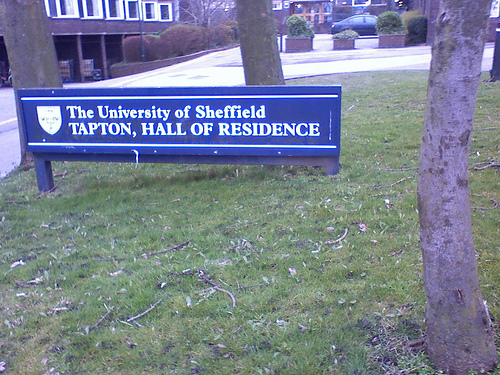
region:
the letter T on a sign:
[61, 100, 78, 121]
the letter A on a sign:
[76, 123, 88, 138]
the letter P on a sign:
[86, 120, 98, 135]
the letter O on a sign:
[107, 120, 119, 136]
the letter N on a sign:
[118, 120, 130, 134]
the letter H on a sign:
[140, 120, 154, 138]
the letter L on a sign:
[162, 120, 176, 135]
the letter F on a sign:
[201, 119, 214, 136]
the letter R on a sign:
[218, 121, 230, 138]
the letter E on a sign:
[229, 120, 241, 137]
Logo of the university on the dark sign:
[33, 102, 63, 137]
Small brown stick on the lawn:
[192, 265, 247, 310]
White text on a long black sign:
[57, 100, 322, 142]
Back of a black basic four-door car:
[327, 13, 383, 36]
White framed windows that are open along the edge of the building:
[45, 0, 177, 27]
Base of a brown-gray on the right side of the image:
[415, 0, 499, 374]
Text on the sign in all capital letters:
[62, 118, 328, 143]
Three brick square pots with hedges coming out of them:
[278, 16, 409, 59]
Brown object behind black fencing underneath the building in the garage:
[55, 54, 100, 86]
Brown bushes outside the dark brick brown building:
[117, 23, 237, 66]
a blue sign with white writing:
[15, 88, 341, 189]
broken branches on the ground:
[92, 262, 234, 327]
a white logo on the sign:
[35, 105, 61, 135]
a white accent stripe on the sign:
[27, 141, 336, 148]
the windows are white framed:
[43, 0, 172, 22]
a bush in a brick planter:
[331, 29, 355, 48]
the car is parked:
[330, 15, 381, 35]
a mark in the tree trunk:
[457, 127, 469, 147]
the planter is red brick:
[281, 36, 311, 53]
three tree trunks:
[2, 3, 495, 370]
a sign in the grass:
[20, 55, 362, 203]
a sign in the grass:
[24, 59, 349, 179]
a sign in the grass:
[33, 85, 301, 227]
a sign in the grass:
[30, 50, 341, 190]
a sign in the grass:
[21, 44, 330, 181]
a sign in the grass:
[19, 54, 311, 189]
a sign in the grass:
[25, 56, 270, 196]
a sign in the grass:
[39, 67, 321, 233]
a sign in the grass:
[29, 21, 384, 198]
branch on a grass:
[125, 287, 170, 325]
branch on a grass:
[148, 230, 191, 260]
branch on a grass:
[194, 264, 237, 318]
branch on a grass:
[314, 218, 350, 256]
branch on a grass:
[385, 170, 410, 195]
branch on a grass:
[470, 153, 496, 179]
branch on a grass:
[15, 260, 65, 302]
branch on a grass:
[82, 300, 116, 333]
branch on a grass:
[32, 193, 66, 246]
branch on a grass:
[55, 165, 87, 180]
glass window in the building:
[46, 0, 61, 16]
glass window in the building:
[110, 0, 121, 17]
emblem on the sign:
[25, 102, 67, 139]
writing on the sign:
[55, 100, 322, 150]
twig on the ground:
[106, 286, 177, 346]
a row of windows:
[40, 5, 180, 22]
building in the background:
[51, 3, 190, 71]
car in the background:
[319, 9, 381, 34]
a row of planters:
[275, 19, 415, 56]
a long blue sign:
[11, 83, 346, 175]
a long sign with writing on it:
[9, 78, 346, 170]